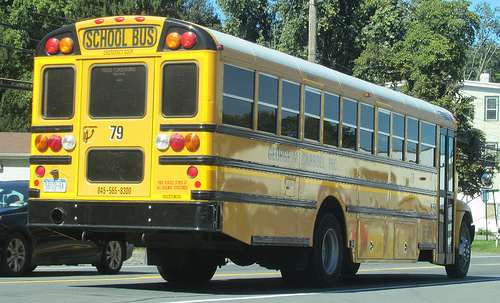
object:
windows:
[41, 59, 438, 171]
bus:
[26, 15, 475, 287]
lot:
[1, 253, 499, 302]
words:
[84, 28, 153, 47]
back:
[26, 16, 215, 234]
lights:
[33, 17, 200, 189]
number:
[109, 125, 123, 141]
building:
[381, 74, 499, 232]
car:
[0, 180, 133, 276]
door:
[438, 127, 456, 265]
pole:
[307, 0, 319, 63]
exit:
[76, 58, 154, 198]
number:
[97, 186, 132, 195]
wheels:
[155, 213, 471, 286]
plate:
[42, 178, 66, 193]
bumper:
[26, 198, 220, 233]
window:
[482, 95, 499, 120]